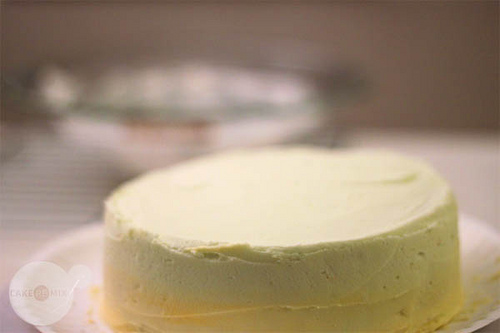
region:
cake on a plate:
[34, 103, 466, 329]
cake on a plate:
[283, 124, 489, 291]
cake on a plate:
[275, 118, 495, 325]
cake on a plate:
[52, 179, 487, 321]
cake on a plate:
[83, 142, 315, 332]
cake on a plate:
[263, 110, 481, 327]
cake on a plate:
[255, 115, 499, 312]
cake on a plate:
[45, 190, 365, 332]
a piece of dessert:
[45, 162, 446, 332]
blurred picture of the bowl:
[16, 27, 374, 163]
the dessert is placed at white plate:
[26, 213, 117, 332]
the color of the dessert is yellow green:
[168, 201, 459, 298]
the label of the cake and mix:
[8, 261, 79, 332]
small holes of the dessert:
[374, 239, 429, 308]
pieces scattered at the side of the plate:
[456, 247, 498, 332]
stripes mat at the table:
[10, 145, 100, 224]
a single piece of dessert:
[88, 137, 463, 312]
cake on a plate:
[42, 154, 496, 330]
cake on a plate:
[20, 140, 442, 331]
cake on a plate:
[48, 134, 493, 331]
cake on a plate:
[39, 142, 489, 330]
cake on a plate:
[58, 170, 466, 330]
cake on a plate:
[91, 134, 461, 332]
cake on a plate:
[29, 130, 458, 328]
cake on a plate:
[39, 131, 469, 332]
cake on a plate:
[91, 163, 468, 332]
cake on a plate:
[38, 130, 440, 331]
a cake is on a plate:
[99, 144, 466, 331]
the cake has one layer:
[91, 141, 468, 327]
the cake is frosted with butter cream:
[103, 142, 461, 332]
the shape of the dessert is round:
[98, 142, 462, 332]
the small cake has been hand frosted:
[96, 143, 466, 331]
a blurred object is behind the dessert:
[39, 47, 329, 160]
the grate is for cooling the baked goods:
[4, 66, 343, 251]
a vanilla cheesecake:
[98, 172, 458, 319]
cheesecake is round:
[116, 205, 455, 319]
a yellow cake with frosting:
[119, 147, 449, 332]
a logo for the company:
[18, 251, 105, 332]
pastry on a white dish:
[466, 236, 498, 319]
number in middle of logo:
[32, 282, 53, 311]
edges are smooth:
[139, 256, 455, 332]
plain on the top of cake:
[116, 142, 428, 250]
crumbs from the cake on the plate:
[86, 280, 99, 332]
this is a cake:
[73, 17, 438, 284]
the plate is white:
[17, 214, 111, 296]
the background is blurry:
[70, 63, 227, 114]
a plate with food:
[57, 197, 207, 329]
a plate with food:
[319, 180, 460, 300]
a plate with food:
[115, 183, 357, 328]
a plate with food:
[275, 193, 467, 329]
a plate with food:
[300, 126, 499, 325]